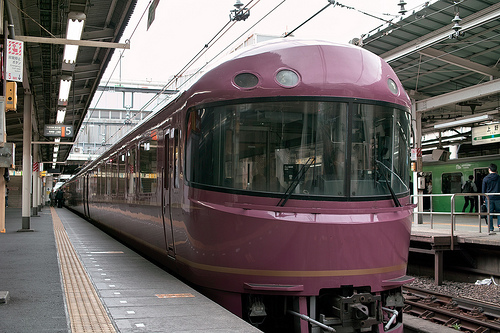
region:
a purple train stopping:
[38, 35, 420, 332]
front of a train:
[183, 25, 435, 315]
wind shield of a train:
[194, 90, 431, 197]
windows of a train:
[106, 128, 178, 187]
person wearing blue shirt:
[474, 164, 499, 226]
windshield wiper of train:
[255, 151, 422, 218]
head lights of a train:
[223, 55, 413, 95]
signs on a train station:
[31, 120, 80, 140]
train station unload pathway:
[28, 191, 272, 331]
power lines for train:
[63, 55, 121, 162]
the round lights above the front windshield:
[230, 52, 306, 97]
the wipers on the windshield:
[272, 151, 407, 217]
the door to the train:
[156, 119, 178, 257]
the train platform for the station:
[33, 224, 95, 328]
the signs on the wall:
[4, 30, 26, 122]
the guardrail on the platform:
[418, 189, 498, 241]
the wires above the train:
[109, 37, 181, 122]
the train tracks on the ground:
[409, 290, 499, 332]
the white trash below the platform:
[467, 270, 498, 288]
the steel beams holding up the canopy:
[18, 97, 40, 239]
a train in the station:
[108, 78, 425, 331]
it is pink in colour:
[45, 80, 399, 307]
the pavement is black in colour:
[33, 218, 156, 330]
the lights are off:
[221, 67, 323, 100]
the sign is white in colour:
[3, 42, 23, 75]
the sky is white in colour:
[165, 0, 329, 41]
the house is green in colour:
[426, 165, 463, 213]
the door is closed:
[145, 125, 190, 272]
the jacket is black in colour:
[482, 172, 497, 196]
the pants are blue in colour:
[476, 195, 499, 212]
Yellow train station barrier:
[42, 200, 104, 330]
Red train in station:
[47, 48, 428, 303]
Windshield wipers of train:
[257, 149, 408, 214]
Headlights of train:
[218, 64, 413, 106]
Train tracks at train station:
[399, 273, 499, 325]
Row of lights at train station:
[40, 9, 88, 178]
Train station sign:
[41, 119, 81, 146]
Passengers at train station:
[447, 162, 498, 224]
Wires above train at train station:
[160, 2, 362, 62]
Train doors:
[79, 168, 98, 222]